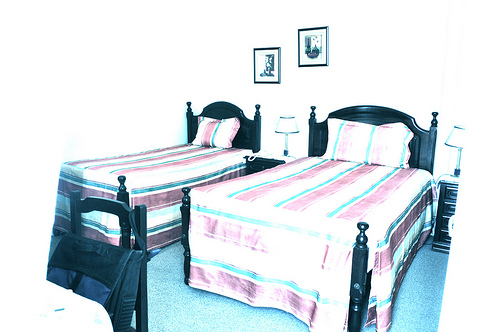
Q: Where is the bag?
A: On the chair.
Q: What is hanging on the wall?
A: Pictures.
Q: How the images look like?
A: Good.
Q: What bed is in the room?
A: Twin bed.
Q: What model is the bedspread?
A: Stripes.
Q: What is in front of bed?
A: Chair.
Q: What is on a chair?
A: Bag.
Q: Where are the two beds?
A: In the bedroom.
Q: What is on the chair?
A: A bag.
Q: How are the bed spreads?
A: Striped.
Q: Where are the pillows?
A: On the beds.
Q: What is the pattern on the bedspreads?
A: Stripes.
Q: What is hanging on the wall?
A: Pictures.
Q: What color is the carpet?
A: Blue.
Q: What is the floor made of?
A: Carpet.